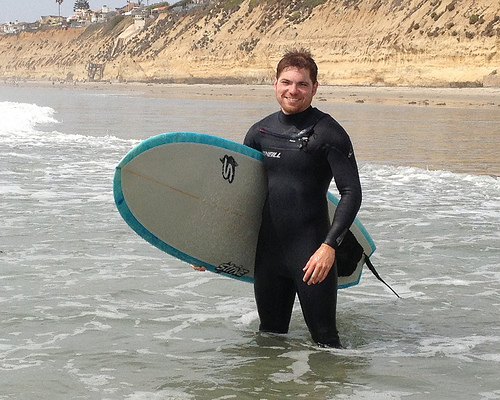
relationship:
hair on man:
[244, 40, 348, 86] [151, 34, 371, 354]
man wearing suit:
[243, 45, 363, 347] [243, 108, 362, 346]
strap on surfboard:
[369, 262, 424, 305] [119, 126, 399, 308]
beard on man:
[277, 86, 312, 111] [242, 53, 362, 348]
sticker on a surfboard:
[219, 152, 239, 181] [109, 130, 376, 288]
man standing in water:
[238, 45, 366, 354] [12, 136, 497, 396]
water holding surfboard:
[12, 136, 497, 396] [104, 128, 385, 295]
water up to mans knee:
[0, 86, 499, 399] [303, 323, 339, 343]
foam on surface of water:
[0, 95, 54, 149] [0, 79, 497, 394]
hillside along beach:
[2, 1, 499, 87] [9, 76, 499, 216]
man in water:
[243, 45, 363, 347] [12, 136, 497, 396]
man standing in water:
[243, 45, 363, 347] [0, 79, 497, 394]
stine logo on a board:
[216, 257, 254, 280] [112, 131, 377, 290]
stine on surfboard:
[216, 259, 249, 279] [131, 131, 333, 305]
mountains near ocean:
[104, 6, 493, 123] [1, 77, 498, 397]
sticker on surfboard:
[219, 154, 236, 184] [114, 117, 426, 310]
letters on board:
[216, 257, 254, 286] [84, 115, 389, 354]